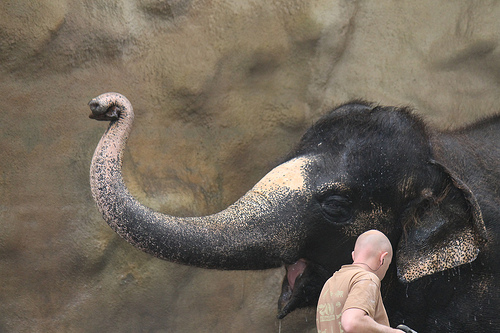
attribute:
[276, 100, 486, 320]
head — grey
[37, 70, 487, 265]
elephant — young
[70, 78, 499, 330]
elephant — small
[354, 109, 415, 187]
hair — black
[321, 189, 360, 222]
eye — black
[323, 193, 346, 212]
eye — open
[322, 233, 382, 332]
shirt — brown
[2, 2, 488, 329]
rock wall — man made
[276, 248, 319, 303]
tongue — pink